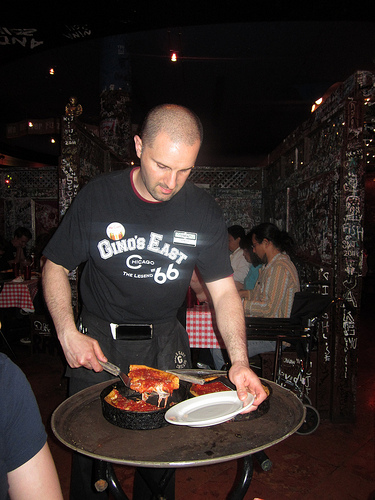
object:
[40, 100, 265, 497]
man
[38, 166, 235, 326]
shirt